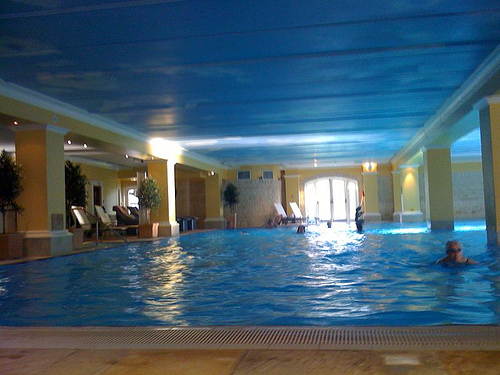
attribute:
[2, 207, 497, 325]
pool — indoor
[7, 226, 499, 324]
water — blue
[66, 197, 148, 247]
chairs — left side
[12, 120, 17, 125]
lighting — recessed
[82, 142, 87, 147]
lighting — recessed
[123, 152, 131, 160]
lighting — recessed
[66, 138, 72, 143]
lighting — recessed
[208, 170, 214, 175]
lighting — recessed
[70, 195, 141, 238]
chair — white, large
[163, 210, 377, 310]
pool — swimming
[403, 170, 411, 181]
fixture — lighted, light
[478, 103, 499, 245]
pillar — neutral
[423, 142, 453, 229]
pillar — neutral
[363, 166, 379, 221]
pillar — neutral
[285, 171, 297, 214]
pillar — neutral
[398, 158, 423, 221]
pillar — neutral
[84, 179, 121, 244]
doorway — white, trimmed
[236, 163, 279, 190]
vents — white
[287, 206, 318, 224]
chair — white, large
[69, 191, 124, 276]
chair — white, lounge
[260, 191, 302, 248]
chair — white, lounge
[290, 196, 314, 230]
chair — white, lounge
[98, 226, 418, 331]
pool — swimming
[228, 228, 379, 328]
water — blue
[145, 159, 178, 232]
column — yellow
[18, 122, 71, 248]
column — yellow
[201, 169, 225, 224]
column — yellow